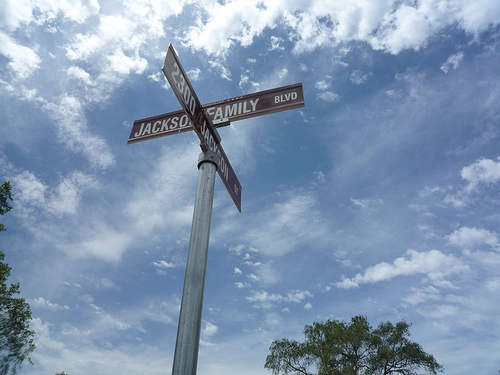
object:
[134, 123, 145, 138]
alphabet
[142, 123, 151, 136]
alphabet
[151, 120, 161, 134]
alphabet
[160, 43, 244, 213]
plate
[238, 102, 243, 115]
alphabet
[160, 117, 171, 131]
alphabet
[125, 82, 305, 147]
plate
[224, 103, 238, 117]
alphabet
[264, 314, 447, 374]
leaves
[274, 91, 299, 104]
writing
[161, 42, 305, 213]
sign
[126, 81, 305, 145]
sign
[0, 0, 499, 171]
sky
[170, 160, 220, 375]
pole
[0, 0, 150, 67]
clouds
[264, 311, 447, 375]
tree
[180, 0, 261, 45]
clouds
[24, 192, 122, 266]
clouds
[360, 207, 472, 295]
clouds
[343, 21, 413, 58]
clouds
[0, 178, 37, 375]
trees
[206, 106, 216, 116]
letters